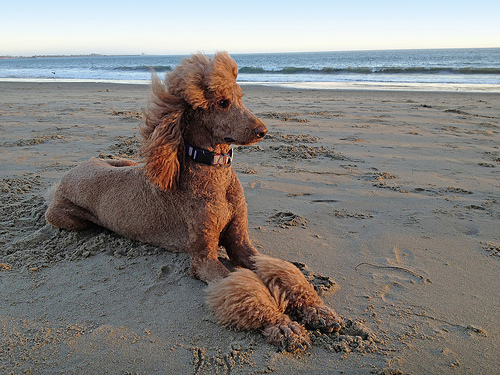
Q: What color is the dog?
A: Brown.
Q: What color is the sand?
A: Brown.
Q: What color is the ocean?
A: Blue.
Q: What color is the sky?
A: BLue.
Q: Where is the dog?
A: At the beach.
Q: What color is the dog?
A: Brown.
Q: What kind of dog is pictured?
A: Poodle.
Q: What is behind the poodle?
A: The ocean.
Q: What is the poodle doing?
A: Laying in the sand.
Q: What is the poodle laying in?
A: Sand.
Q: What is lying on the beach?
A: A dog.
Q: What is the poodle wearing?
A: A collar.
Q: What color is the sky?
A: Blue.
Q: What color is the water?
A: Blue.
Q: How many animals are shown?
A: 1.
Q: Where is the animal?
A: On the sand.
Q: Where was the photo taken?
A: Beach.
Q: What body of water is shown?
A: Ocean.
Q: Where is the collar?
A: On dog's neck.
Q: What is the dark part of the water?
A: Wave.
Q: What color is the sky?
A: Blue.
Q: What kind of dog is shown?
A: Poodle.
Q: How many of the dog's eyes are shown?
A: 1.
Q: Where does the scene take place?
A: At the beach.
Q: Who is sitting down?
A: A dog.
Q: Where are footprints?
A: On the sand.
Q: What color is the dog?
A: Light brown.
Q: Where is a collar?
A: Around dog's neck.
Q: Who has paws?
A: The dog.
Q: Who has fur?
A: A dog.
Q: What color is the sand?
A: Beige.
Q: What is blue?
A: Ocean.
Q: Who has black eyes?
A: Dog.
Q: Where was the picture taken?
A: On a beach.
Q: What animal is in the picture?
A: A dog.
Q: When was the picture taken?
A: During the day.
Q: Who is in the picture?
A: Just the dog.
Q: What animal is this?
A: Poodle.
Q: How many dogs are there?
A: One.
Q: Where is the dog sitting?
A: On the sand.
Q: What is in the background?
A: Ocean.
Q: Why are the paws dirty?
A: Covered in sand.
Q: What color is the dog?
A: Brown.